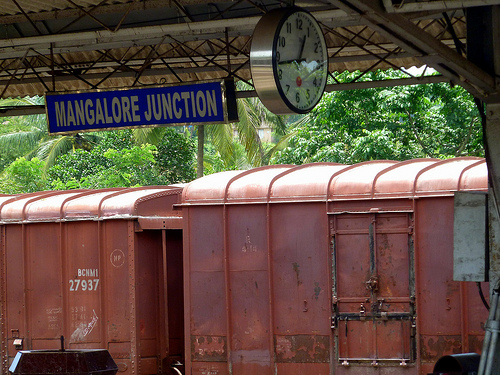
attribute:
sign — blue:
[41, 82, 228, 135]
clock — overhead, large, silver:
[249, 5, 332, 115]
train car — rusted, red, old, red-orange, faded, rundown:
[182, 154, 494, 374]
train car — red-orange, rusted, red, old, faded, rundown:
[4, 177, 195, 374]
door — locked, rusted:
[325, 208, 420, 369]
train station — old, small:
[2, 2, 491, 370]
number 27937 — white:
[66, 278, 99, 293]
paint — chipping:
[275, 333, 331, 367]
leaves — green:
[210, 74, 480, 159]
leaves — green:
[2, 126, 199, 177]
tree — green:
[245, 61, 490, 162]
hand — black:
[299, 31, 308, 62]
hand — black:
[276, 52, 308, 65]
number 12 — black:
[293, 17, 304, 32]